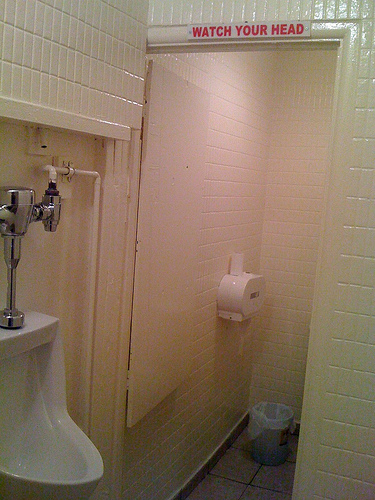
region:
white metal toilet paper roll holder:
[219, 264, 266, 328]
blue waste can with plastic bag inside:
[247, 400, 295, 467]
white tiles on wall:
[272, 236, 302, 380]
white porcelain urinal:
[0, 316, 102, 498]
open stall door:
[116, 52, 199, 494]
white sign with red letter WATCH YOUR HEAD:
[186, 20, 315, 38]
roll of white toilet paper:
[227, 246, 245, 275]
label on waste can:
[278, 423, 294, 450]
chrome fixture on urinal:
[5, 187, 64, 333]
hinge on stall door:
[120, 368, 135, 390]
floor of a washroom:
[234, 466, 260, 481]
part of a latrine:
[66, 422, 88, 455]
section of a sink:
[25, 420, 44, 474]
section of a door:
[126, 369, 137, 390]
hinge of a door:
[106, 372, 133, 415]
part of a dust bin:
[254, 431, 277, 463]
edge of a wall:
[209, 433, 235, 476]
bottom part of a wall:
[180, 458, 212, 498]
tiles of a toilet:
[259, 477, 270, 493]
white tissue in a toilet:
[234, 256, 243, 271]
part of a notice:
[260, 16, 288, 36]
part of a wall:
[164, 439, 199, 473]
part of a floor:
[215, 466, 233, 489]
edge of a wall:
[202, 458, 213, 469]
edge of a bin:
[259, 414, 280, 424]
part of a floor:
[219, 458, 250, 492]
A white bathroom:
[14, 67, 349, 488]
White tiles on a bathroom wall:
[212, 129, 315, 255]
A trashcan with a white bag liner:
[238, 389, 300, 475]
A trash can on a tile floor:
[233, 385, 290, 498]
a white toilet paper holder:
[207, 272, 272, 337]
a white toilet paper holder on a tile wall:
[200, 264, 263, 360]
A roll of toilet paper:
[218, 239, 250, 291]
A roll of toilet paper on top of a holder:
[225, 248, 272, 355]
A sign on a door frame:
[174, 17, 322, 55]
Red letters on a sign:
[185, 19, 325, 41]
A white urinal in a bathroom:
[12, 283, 131, 493]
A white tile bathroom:
[7, 184, 307, 494]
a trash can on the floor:
[232, 382, 293, 483]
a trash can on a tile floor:
[225, 386, 292, 498]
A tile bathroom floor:
[180, 445, 279, 497]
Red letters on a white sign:
[145, 8, 328, 75]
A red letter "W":
[187, 20, 203, 44]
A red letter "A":
[202, 21, 210, 45]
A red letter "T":
[207, 23, 216, 42]